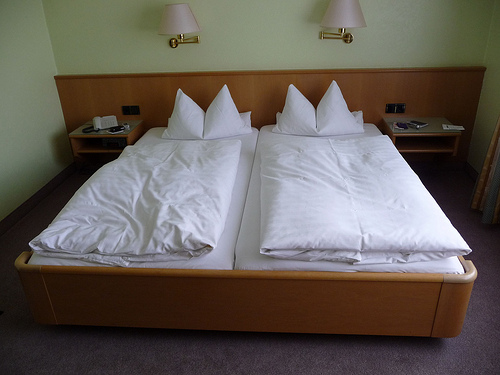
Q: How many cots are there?
A: 2.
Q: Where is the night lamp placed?
A: In the wall.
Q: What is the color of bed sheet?
A: White.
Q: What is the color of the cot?
A: Brown.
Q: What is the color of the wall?
A: Light yellow.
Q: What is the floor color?
A: Grey.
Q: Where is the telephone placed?
A: On the side of the cot.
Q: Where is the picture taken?
A: In a bedroom.